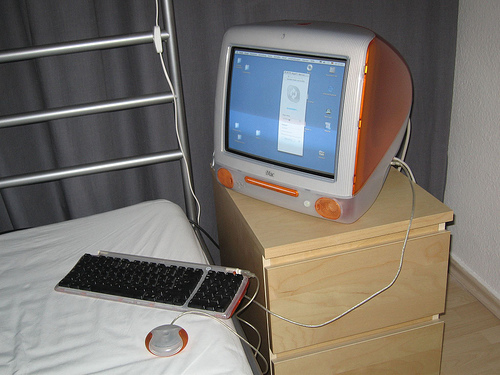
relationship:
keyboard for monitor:
[54, 249, 252, 320] [210, 19, 415, 225]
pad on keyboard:
[188, 270, 243, 312] [54, 249, 252, 320]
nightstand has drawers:
[214, 166, 455, 375] [265, 231, 452, 375]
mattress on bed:
[1, 198, 256, 375] [0, 0, 268, 374]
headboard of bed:
[0, 0, 199, 235] [0, 0, 268, 374]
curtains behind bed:
[1, 0, 459, 265] [0, 0, 268, 374]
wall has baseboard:
[443, 2, 499, 318] [446, 254, 499, 321]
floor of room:
[440, 272, 500, 374] [0, 0, 499, 374]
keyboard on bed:
[54, 249, 252, 320] [0, 0, 268, 374]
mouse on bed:
[144, 326, 189, 358] [0, 0, 268, 374]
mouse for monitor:
[144, 326, 189, 358] [210, 19, 415, 225]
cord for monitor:
[244, 162, 417, 328] [210, 19, 415, 225]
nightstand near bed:
[214, 166, 455, 375] [0, 0, 268, 374]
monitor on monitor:
[224, 44, 348, 180] [210, 19, 415, 225]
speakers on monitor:
[217, 167, 341, 221] [210, 19, 415, 225]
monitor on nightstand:
[210, 19, 415, 225] [214, 166, 455, 375]